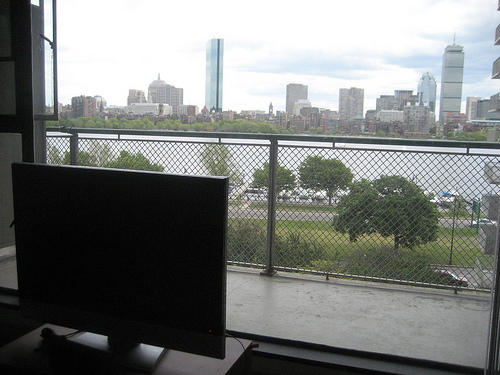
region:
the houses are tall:
[105, 38, 490, 113]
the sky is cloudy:
[235, 8, 355, 63]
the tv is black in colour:
[13, 162, 238, 350]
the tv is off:
[6, 157, 238, 359]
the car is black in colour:
[441, 270, 470, 283]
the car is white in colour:
[460, 210, 499, 227]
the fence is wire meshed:
[255, 130, 490, 283]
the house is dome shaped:
[147, 71, 168, 89]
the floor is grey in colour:
[264, 273, 386, 348]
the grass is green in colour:
[293, 213, 340, 247]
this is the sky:
[317, 40, 352, 57]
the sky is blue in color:
[410, 55, 435, 70]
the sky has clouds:
[316, 23, 408, 85]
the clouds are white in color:
[260, 12, 306, 42]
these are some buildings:
[271, 62, 445, 120]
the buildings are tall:
[278, 39, 453, 127]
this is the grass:
[316, 223, 328, 233]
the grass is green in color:
[297, 220, 310, 232]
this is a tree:
[313, 163, 451, 256]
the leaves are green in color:
[358, 186, 387, 208]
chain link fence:
[39, 125, 499, 301]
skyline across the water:
[57, 25, 499, 137]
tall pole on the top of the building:
[450, 31, 460, 46]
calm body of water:
[58, 125, 498, 199]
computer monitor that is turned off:
[14, 153, 239, 366]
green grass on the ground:
[233, 217, 487, 276]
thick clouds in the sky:
[54, 6, 497, 111]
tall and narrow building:
[197, 36, 230, 113]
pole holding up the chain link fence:
[260, 139, 285, 278]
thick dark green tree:
[326, 174, 436, 256]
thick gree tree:
[329, 173, 448, 258]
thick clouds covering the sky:
[62, 5, 498, 116]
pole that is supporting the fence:
[261, 136, 287, 274]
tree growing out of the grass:
[327, 172, 447, 264]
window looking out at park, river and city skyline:
[6, 5, 492, 365]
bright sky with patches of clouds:
[66, 0, 491, 130]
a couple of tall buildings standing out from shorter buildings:
[65, 30, 495, 135]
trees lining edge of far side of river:
[55, 110, 490, 140]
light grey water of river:
[45, 130, 495, 195]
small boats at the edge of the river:
[240, 151, 491, 207]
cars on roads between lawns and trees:
[235, 155, 490, 300]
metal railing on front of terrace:
[51, 130, 491, 365]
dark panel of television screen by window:
[5, 160, 225, 371]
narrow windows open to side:
[1, 0, 57, 298]